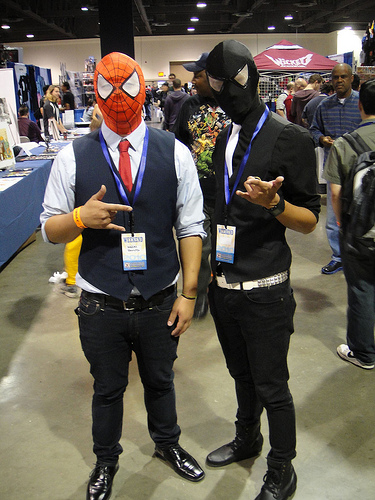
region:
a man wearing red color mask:
[40, 53, 205, 497]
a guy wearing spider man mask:
[40, 54, 205, 496]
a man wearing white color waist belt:
[203, 41, 313, 496]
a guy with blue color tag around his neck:
[203, 44, 309, 497]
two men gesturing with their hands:
[40, 40, 324, 493]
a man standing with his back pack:
[325, 78, 373, 375]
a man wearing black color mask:
[201, 43, 324, 495]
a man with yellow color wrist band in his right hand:
[39, 57, 206, 306]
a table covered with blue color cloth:
[4, 157, 47, 268]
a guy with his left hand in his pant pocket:
[323, 80, 371, 381]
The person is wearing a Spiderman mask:
[91, 51, 148, 131]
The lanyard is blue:
[97, 127, 152, 215]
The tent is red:
[250, 40, 336, 74]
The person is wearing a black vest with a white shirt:
[47, 52, 208, 301]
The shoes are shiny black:
[79, 446, 203, 499]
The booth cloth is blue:
[0, 135, 68, 270]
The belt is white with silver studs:
[213, 272, 288, 288]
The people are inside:
[48, 41, 372, 478]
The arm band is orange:
[70, 205, 84, 233]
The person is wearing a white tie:
[223, 120, 239, 179]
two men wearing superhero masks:
[46, 50, 325, 489]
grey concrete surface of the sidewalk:
[319, 384, 374, 493]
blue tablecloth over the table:
[12, 180, 33, 216]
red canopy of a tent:
[254, 35, 333, 71]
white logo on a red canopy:
[262, 52, 313, 68]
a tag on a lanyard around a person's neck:
[88, 144, 161, 272]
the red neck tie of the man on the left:
[100, 135, 136, 197]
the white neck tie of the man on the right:
[222, 118, 237, 180]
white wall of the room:
[40, 49, 78, 58]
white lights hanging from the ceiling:
[188, 0, 221, 40]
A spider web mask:
[83, 50, 140, 127]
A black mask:
[195, 33, 267, 115]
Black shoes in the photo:
[52, 433, 208, 496]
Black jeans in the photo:
[89, 321, 181, 448]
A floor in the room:
[33, 356, 78, 473]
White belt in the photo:
[214, 273, 289, 291]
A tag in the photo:
[210, 220, 245, 286]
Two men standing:
[60, 44, 316, 498]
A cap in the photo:
[181, 47, 209, 76]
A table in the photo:
[5, 153, 36, 200]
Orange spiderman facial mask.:
[92, 47, 145, 131]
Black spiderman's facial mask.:
[207, 40, 258, 121]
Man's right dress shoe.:
[155, 443, 203, 480]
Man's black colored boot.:
[248, 455, 299, 499]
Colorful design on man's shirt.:
[188, 112, 228, 174]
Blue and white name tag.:
[215, 224, 235, 266]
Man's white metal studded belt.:
[213, 273, 292, 287]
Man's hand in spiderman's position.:
[84, 186, 134, 236]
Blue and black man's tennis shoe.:
[320, 258, 342, 275]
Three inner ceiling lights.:
[186, 1, 209, 33]